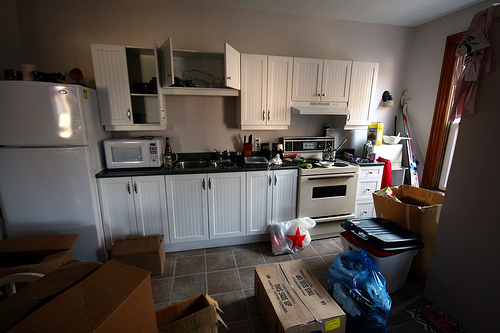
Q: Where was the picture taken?
A: In a kitchen.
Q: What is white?
A: Fridge.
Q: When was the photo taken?
A: Daytime.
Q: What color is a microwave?
A: White.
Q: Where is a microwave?
A: On the counter.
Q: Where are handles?
A: On cabinets.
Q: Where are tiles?
A: On the floor.